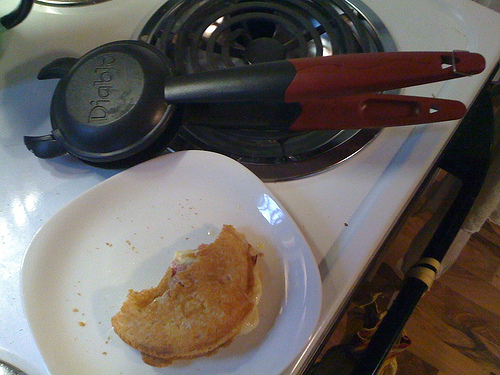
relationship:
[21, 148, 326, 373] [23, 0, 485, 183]
plate and cooker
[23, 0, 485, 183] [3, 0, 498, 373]
cooker on top pf stove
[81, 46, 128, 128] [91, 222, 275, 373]
letters of sandwich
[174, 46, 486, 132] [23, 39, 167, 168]
handle on circular panel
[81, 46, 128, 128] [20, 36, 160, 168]
letters over circular panel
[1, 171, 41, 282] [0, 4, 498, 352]
light reflection off white surface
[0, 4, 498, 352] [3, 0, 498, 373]
white surface of stove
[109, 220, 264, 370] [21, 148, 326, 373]
sandwich on a plate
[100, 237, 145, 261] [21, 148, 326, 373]
bread crumbs on a plate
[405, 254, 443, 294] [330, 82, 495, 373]
yellow cord wrapped around a pole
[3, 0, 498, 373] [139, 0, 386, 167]
stove has coil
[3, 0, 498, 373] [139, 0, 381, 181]
stove has coil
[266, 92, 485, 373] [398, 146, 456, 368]
oven has handle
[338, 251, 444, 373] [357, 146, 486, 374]
napkin on handle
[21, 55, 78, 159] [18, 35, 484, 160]
curved hinges on top of cooking tool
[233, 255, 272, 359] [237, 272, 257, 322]
filling spilling out of sandwich